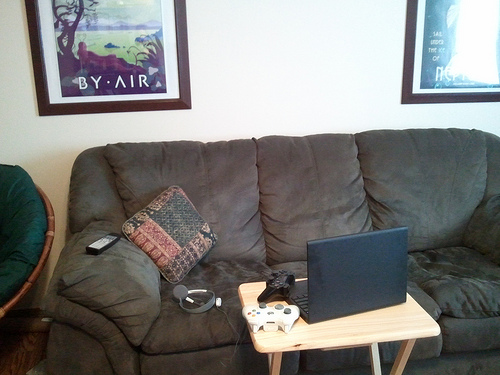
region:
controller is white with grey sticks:
[231, 293, 326, 345]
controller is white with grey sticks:
[231, 300, 288, 325]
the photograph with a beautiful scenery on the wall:
[15, 11, 217, 115]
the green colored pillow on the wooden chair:
[7, 157, 57, 339]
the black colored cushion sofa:
[49, 128, 491, 368]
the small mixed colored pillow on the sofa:
[118, 184, 234, 290]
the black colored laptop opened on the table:
[285, 221, 426, 329]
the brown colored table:
[227, 276, 461, 372]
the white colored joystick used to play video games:
[242, 298, 303, 346]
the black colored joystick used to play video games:
[254, 262, 301, 303]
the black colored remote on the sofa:
[68, 229, 128, 284]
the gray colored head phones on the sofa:
[168, 277, 232, 339]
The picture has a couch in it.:
[60, 146, 496, 342]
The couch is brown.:
[70, 150, 495, 311]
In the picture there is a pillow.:
[132, 170, 214, 286]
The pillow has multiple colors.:
[120, 200, 205, 275]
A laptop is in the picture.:
[280, 225, 412, 317]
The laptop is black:
[287, 255, 412, 325]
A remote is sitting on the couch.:
[88, 221, 130, 264]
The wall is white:
[213, 58, 382, 121]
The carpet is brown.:
[5, 325, 39, 373]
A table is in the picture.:
[246, 272, 416, 372]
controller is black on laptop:
[257, 260, 302, 296]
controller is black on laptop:
[228, 248, 291, 301]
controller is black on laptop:
[250, 254, 324, 322]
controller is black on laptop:
[251, 255, 288, 306]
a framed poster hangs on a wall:
[30, 0, 195, 110]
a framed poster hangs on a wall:
[399, 0, 495, 102]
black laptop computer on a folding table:
[275, 230, 443, 333]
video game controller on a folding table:
[243, 294, 308, 340]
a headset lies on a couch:
[166, 269, 229, 329]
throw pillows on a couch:
[123, 180, 220, 286]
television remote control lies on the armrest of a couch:
[87, 223, 124, 268]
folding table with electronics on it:
[232, 222, 438, 371]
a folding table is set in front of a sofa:
[57, 137, 498, 374]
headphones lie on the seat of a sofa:
[165, 274, 233, 330]